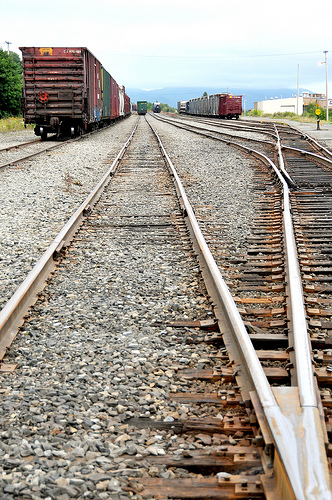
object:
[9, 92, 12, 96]
leaf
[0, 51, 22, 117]
plant